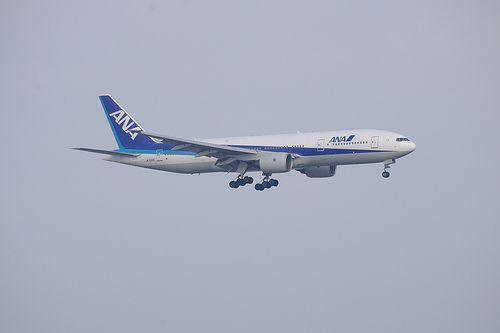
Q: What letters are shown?
A: ANA.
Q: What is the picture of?
A: Airplane.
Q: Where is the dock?
A: No dock.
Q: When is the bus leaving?
A: No bus.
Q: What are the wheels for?
A: Landing.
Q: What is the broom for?
A: No broom.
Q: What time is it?
A: Afternoon.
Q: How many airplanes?
A: One.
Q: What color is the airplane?
A: White and blue.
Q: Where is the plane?
A: In the air.